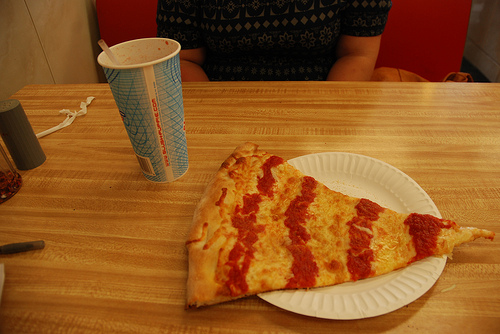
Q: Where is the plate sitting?
A: The table.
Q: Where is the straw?
A: The cup.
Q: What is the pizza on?
A: A plate.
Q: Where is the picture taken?
A: A restaurant.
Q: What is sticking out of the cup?
A: Straw.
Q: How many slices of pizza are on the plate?
A: One.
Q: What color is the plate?
A: White.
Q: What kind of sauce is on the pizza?
A: Tomato.